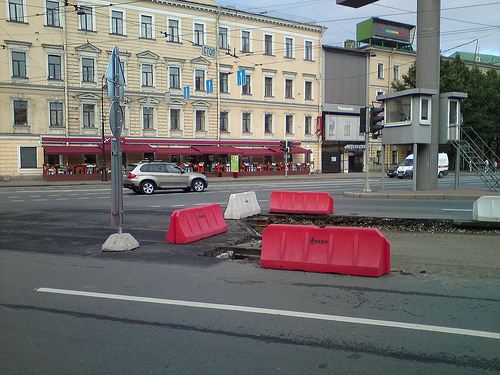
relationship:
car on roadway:
[121, 158, 209, 194] [2, 170, 499, 371]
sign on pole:
[107, 102, 126, 139] [115, 60, 122, 230]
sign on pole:
[107, 102, 126, 139] [98, 138, 137, 235]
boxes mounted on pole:
[353, 82, 477, 166] [379, 2, 465, 109]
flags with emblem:
[176, 70, 253, 101] [237, 71, 244, 83]